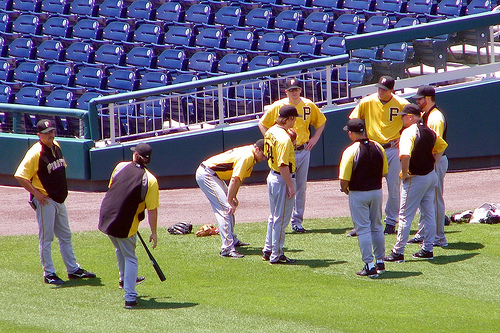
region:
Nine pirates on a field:
[18, 69, 456, 304]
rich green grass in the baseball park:
[1, 218, 494, 332]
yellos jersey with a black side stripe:
[199, 144, 256, 183]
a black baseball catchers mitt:
[167, 210, 220, 245]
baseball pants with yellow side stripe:
[256, 166, 295, 262]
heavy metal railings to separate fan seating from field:
[4, 53, 260, 140]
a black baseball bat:
[136, 219, 169, 291]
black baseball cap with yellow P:
[282, 73, 305, 96]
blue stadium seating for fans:
[0, 0, 315, 111]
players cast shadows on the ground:
[144, 218, 491, 322]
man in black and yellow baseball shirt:
[13, 116, 98, 287]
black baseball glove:
[166, 217, 193, 238]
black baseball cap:
[33, 117, 56, 135]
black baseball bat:
[138, 229, 173, 287]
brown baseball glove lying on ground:
[193, 221, 219, 245]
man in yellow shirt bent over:
[194, 138, 266, 256]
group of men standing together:
[333, 73, 449, 278]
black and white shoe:
[39, 272, 66, 287]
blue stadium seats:
[3, 56, 91, 101]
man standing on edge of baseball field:
[261, 101, 304, 266]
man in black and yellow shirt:
[15, 101, 90, 290]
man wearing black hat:
[8, 101, 98, 294]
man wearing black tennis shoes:
[10, 111, 100, 286]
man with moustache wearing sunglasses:
[15, 100, 96, 296]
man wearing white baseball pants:
[12, 107, 100, 299]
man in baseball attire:
[14, 110, 100, 292]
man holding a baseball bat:
[96, 125, 168, 314]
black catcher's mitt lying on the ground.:
[163, 217, 196, 240]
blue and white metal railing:
[87, 49, 352, 145]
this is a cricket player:
[12, 121, 97, 284]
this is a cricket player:
[87, 140, 162, 306]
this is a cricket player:
[195, 120, 270, 260]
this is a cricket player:
[260, 100, 305, 267]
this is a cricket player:
[261, 80, 331, 233]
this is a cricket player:
[336, 118, 391, 283]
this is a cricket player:
[391, 106, 442, 261]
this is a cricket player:
[410, 88, 457, 261]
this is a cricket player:
[355, 76, 400, 229]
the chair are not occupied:
[3, 2, 490, 145]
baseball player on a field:
[13, 110, 98, 295]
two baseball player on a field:
[21, 112, 173, 312]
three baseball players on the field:
[7, 108, 265, 310]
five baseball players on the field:
[13, 76, 329, 311]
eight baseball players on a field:
[12, 74, 480, 311]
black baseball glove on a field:
[162, 220, 197, 235]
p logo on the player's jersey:
[298, 104, 313, 122]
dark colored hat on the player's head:
[32, 119, 59, 132]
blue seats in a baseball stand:
[3, 35, 423, 131]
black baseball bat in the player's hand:
[131, 216, 177, 283]